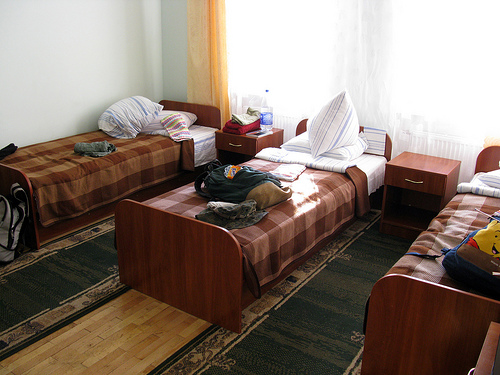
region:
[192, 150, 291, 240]
pile of clothes on the bed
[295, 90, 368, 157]
blue and white pillow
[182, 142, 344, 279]
tan plaid blanket on bed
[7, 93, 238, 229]
bed in corner of room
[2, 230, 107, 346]
green rug on ground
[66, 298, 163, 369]
wooden floors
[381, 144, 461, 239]
wooden nightstand in between two beds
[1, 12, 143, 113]
bare white wall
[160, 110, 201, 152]
striped towel on bed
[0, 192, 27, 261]
black and white backpack near bed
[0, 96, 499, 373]
three small beds in the room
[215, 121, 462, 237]
a set of night stands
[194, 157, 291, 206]
a green backpack sitting on the bed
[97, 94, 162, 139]
messed up pillow on the left bed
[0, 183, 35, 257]
a backpack propped up against the bed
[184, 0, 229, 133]
a yellow curtain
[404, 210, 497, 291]
a Winnie the Pooh backpack on the right bed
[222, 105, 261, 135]
a small stack of clothing on the left night stand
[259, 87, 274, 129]
a bottle of water on the night stand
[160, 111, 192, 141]
a multi-colored cloth on the left bed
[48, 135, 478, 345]
Three beds line up in a row.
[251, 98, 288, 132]
A bottle of water is on the night stand.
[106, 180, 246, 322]
The footboard is wooden.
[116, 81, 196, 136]
The bed has two pillows on top.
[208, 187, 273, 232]
Clothing is on the middle bed.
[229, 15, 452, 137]
The sheer curtains are white.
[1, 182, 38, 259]
A bag pack lays on the floor by the bed.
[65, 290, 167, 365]
The floor is made of wood.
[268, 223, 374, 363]
The green rug is long.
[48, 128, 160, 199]
The spread is brown with long stripes.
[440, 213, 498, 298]
winnie the pooh backpack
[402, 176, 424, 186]
brass plated drawer handle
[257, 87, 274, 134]
large water bottle with blue cap and label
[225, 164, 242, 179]
orange and blue box of candy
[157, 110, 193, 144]
small multi-colored towel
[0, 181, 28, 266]
grey backpack with black trim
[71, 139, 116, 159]
small grey satchel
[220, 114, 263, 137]
ruby red folded bed sheet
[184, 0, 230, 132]
peach colored curtain panel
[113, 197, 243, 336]
wooden footboard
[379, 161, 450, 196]
a brown wooden drawer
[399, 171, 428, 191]
the handle of a drawer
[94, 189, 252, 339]
a wooden foot board on the bed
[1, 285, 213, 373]
a brown wooden floor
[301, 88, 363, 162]
a white striped pillow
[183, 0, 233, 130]
an orange curtain on the window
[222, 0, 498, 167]
white curtains on the window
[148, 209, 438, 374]
a green and white rug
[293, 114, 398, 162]
a brown wooden head board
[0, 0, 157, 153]
a white wall in the room